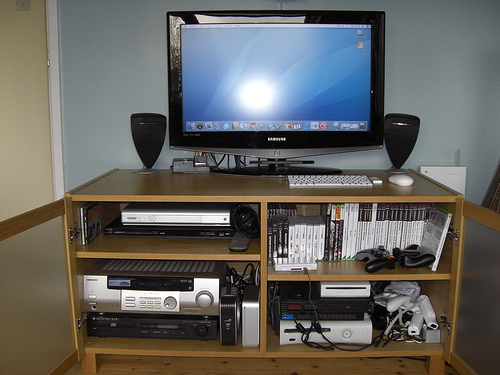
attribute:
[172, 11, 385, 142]
tv — flatscreen, mini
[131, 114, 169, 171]
speaker — black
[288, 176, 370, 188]
keyboard — white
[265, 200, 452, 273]
shelf — wooden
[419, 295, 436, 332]
wii — white, black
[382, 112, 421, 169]
speakers — black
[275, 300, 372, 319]
playstation — black